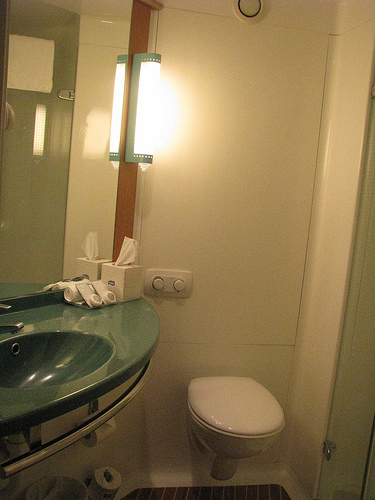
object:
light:
[131, 52, 169, 165]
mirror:
[0, 1, 81, 300]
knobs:
[57, 84, 82, 104]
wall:
[146, 1, 332, 476]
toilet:
[187, 371, 286, 456]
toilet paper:
[83, 416, 118, 447]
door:
[2, 0, 81, 300]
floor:
[109, 478, 300, 498]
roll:
[93, 459, 123, 491]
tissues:
[117, 229, 143, 266]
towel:
[63, 277, 91, 306]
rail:
[2, 357, 155, 480]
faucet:
[8, 316, 25, 334]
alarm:
[236, 1, 263, 23]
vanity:
[144, 25, 195, 170]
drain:
[11, 340, 21, 359]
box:
[98, 259, 147, 301]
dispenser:
[98, 262, 141, 302]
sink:
[0, 321, 116, 395]